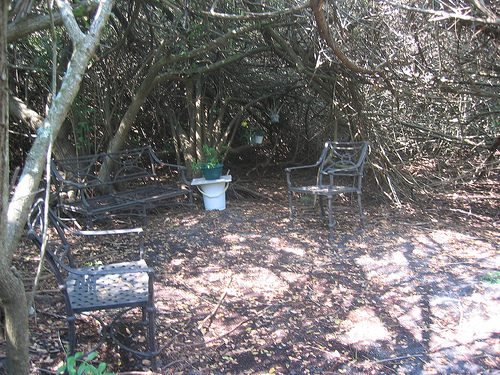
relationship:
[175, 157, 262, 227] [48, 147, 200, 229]
bucket next to bench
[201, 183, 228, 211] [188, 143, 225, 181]
bucket with plant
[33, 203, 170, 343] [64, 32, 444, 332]
metal bench in woods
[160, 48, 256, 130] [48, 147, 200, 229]
trees over bench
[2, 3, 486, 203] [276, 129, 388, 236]
trees next to bench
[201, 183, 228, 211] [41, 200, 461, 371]
bucket on ground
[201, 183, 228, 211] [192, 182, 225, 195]
bucket with handle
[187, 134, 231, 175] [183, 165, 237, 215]
plant on top of table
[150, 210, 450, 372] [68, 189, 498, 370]
shadows on dirt clearing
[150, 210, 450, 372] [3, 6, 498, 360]
shadows of tree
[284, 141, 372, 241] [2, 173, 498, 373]
bench on ground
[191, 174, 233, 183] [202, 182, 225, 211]
board on bucket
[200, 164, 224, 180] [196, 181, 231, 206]
bucket on bucket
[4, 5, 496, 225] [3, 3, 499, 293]
trees in background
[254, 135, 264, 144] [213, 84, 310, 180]
bucket hanging from tree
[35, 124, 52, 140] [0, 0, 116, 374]
leaf on tree